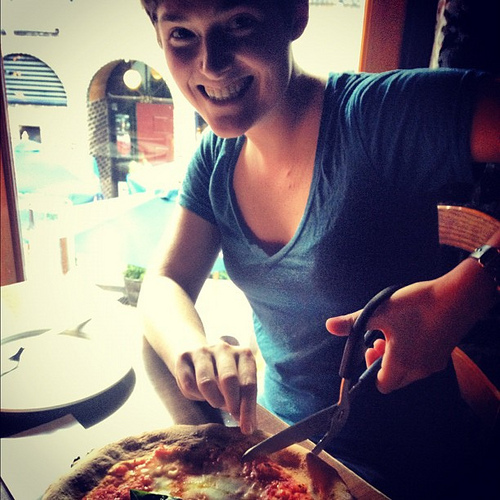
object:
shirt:
[167, 76, 474, 473]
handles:
[339, 283, 399, 396]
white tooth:
[209, 87, 215, 97]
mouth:
[192, 73, 255, 108]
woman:
[101, 4, 498, 494]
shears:
[243, 285, 405, 474]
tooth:
[224, 89, 229, 98]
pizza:
[81, 424, 333, 499]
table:
[23, 285, 67, 325]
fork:
[0, 342, 26, 383]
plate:
[2, 329, 134, 414]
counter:
[11, 417, 63, 495]